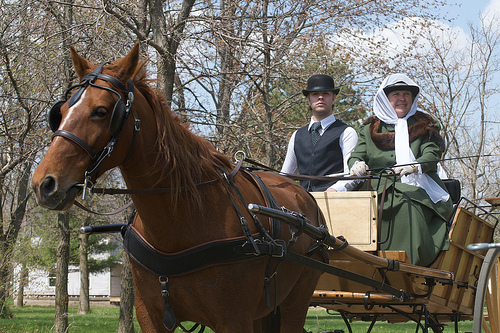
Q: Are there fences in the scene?
A: No, there are no fences.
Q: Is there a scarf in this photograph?
A: Yes, there is a scarf.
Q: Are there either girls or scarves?
A: Yes, there is a scarf.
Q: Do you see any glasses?
A: No, there are no glasses.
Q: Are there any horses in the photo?
A: Yes, there is a horse.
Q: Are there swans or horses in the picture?
A: Yes, there is a horse.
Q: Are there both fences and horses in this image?
A: No, there is a horse but no fences.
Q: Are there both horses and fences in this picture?
A: No, there is a horse but no fences.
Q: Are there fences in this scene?
A: No, there are no fences.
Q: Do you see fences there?
A: No, there are no fences.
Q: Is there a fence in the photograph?
A: No, there are no fences.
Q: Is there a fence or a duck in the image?
A: No, there are no fences or ducks.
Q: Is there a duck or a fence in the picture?
A: No, there are no fences or ducks.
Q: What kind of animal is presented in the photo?
A: The animal is a horse.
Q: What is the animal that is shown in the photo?
A: The animal is a horse.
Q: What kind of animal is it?
A: The animal is a horse.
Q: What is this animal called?
A: This is a horse.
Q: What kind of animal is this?
A: This is a horse.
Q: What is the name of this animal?
A: This is a horse.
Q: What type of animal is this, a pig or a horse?
A: This is a horse.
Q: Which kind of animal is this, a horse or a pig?
A: This is a horse.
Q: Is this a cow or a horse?
A: This is a horse.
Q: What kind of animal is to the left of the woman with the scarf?
A: The animal is a horse.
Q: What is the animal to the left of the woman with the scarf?
A: The animal is a horse.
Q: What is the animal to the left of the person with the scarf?
A: The animal is a horse.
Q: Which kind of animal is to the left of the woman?
A: The animal is a horse.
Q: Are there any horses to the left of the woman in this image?
A: Yes, there is a horse to the left of the woman.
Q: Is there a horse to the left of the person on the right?
A: Yes, there is a horse to the left of the woman.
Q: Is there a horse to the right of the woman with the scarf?
A: No, the horse is to the left of the woman.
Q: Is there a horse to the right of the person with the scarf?
A: No, the horse is to the left of the woman.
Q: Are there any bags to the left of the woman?
A: No, there is a horse to the left of the woman.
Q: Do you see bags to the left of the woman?
A: No, there is a horse to the left of the woman.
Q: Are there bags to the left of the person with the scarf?
A: No, there is a horse to the left of the woman.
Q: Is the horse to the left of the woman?
A: Yes, the horse is to the left of the woman.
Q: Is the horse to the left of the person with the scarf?
A: Yes, the horse is to the left of the woman.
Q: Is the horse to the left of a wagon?
A: No, the horse is to the left of the woman.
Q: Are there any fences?
A: No, there are no fences.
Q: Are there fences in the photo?
A: No, there are no fences.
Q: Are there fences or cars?
A: No, there are no fences or cars.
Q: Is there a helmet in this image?
A: No, there are no helmets.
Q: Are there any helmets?
A: No, there are no helmets.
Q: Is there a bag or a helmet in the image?
A: No, there are no helmets or bags.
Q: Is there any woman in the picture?
A: Yes, there is a woman.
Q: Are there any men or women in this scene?
A: Yes, there is a woman.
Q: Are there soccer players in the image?
A: No, there are no soccer players.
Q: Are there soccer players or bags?
A: No, there are no soccer players or bags.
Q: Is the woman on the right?
A: Yes, the woman is on the right of the image.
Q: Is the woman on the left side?
A: No, the woman is on the right of the image.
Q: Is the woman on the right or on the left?
A: The woman is on the right of the image.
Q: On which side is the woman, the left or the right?
A: The woman is on the right of the image.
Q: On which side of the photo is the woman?
A: The woman is on the right of the image.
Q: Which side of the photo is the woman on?
A: The woman is on the right of the image.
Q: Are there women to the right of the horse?
A: Yes, there is a woman to the right of the horse.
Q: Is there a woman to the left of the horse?
A: No, the woman is to the right of the horse.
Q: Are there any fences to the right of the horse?
A: No, there is a woman to the right of the horse.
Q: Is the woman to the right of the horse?
A: Yes, the woman is to the right of the horse.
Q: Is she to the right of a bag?
A: No, the woman is to the right of the horse.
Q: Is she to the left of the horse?
A: No, the woman is to the right of the horse.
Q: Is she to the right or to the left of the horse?
A: The woman is to the right of the horse.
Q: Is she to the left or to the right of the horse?
A: The woman is to the right of the horse.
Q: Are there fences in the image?
A: No, there are no fences.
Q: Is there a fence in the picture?
A: No, there are no fences.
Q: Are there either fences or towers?
A: No, there are no fences or towers.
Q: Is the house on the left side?
A: Yes, the house is on the left of the image.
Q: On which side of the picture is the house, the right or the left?
A: The house is on the left of the image.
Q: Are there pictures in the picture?
A: No, there are no pictures.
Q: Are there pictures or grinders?
A: No, there are no pictures or grinders.